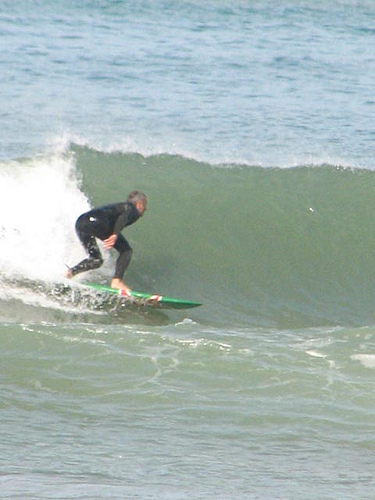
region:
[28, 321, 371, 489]
water is green and murky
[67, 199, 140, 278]
the surfer is wearing a wetsuit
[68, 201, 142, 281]
the wetsuit is black in color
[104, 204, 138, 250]
the surfer's arm is lowered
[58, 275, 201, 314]
the surfboard is green in color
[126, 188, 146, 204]
the surfer has grey hair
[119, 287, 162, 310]
the surfboard has red and white markings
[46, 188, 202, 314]
the surfer is riding a wave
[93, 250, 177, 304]
the surfer is casting a shadow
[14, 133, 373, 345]
the wave is rising high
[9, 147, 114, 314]
the surfer is splashing water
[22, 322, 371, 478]
water is green and clear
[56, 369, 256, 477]
water is green and clear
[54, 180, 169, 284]
surfer in wet suit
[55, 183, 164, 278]
surfer in black wet suit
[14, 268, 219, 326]
man surfing on green and red surf board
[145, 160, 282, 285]
green colored wave in ocean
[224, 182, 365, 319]
green colored wave in ocean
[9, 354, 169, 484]
green colored wave in ocean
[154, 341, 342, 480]
green colored wave in ocean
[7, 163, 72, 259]
white foam in green wave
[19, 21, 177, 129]
blue colored water in ocean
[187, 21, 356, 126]
blue colored water in ocean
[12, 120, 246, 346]
surfer riding the awesome waves.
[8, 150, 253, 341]
surfer riding the great waves.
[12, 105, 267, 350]
surfer riding the beautiful waves.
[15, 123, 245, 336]
surfer riding some amazing waves.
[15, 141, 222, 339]
person surfing the awesome waves.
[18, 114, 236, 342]
person surfing the great waves.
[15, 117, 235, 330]
person surfing the beautiful waves.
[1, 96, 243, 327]
person surfing the mighty waves.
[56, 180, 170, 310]
surfer wearing dark clothing.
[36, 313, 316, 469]
some really nice ocean water.